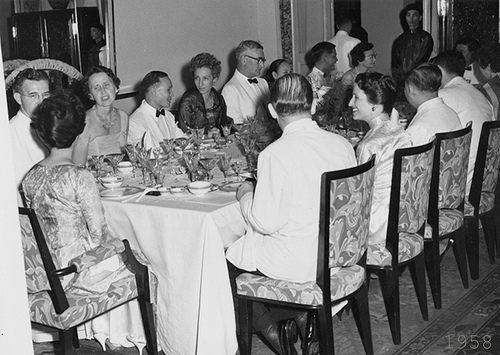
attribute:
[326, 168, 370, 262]
chair — decorative, wooden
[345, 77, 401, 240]
woman — smiling, dark, short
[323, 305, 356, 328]
stilettos — high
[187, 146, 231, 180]
glass — crystal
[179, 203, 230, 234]
table — large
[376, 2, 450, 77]
attendant — assisting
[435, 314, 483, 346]
rug — decorative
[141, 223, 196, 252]
tablecloth — white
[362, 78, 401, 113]
hair — wavy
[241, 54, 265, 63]
glasses — wine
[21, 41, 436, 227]
people — sitting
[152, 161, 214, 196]
bowl — white